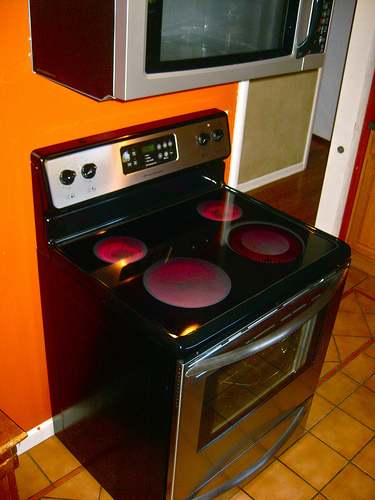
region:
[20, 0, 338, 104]
a microwave oven is mounted above the range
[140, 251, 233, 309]
the burners are a smooth surface which simplifies the top cooking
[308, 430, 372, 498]
the floor is tiled or linoleum yellow in color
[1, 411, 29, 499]
the corner of a wooden table sits next to the stove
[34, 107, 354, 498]
a range sits all the kitchen floor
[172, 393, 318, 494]
a sliding toward the bottom of the range allows for storage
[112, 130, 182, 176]
a modern console the range featuring digital readout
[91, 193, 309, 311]
the 4 burners on top of the range are still hot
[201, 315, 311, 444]
a glass door in front of the stove door allows you to see and while cooking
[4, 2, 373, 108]
microwave is mounted above stovetop range for easy cooking access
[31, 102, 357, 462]
black oven and stove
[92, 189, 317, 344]
electric stove top burners on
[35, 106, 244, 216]
control panel for stove and oven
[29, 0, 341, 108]
wall mounted microwave oven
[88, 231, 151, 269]
ceramic top electric range burner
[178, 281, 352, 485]
silver colored oven door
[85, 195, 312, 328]
four stove burners on electric stove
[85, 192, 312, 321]
range top with burners on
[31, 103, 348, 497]
electric stove with oven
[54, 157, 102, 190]
stove burner control knobs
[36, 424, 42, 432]
speck of orange paint on baseboard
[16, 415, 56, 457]
section of white baseboard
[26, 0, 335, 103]
Microwave oven mounted above stove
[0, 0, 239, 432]
wall is painted bright orange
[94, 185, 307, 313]
four stove burners with red glow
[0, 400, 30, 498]
corner of brown countertop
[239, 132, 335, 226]
wooden floor in hallway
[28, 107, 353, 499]
black and silver stove with oven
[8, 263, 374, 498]
terra cotta colored tile in kitchen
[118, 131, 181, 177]
control plate with clock on stove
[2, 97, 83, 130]
orange kitchen wall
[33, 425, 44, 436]
orange spot on the white baseboard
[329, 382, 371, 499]
tiled kitchen floor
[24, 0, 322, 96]
microwave above the stove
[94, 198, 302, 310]
four electric burners on a stove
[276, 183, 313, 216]
wooden floor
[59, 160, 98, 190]
two dials on the oven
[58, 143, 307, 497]
silver and black kitchen stove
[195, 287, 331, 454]
window on the oven door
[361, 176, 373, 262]
wooden kitchen cabinet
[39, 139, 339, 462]
black stove by orange wall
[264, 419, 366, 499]
tan tiles in kitchen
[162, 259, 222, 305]
hot burner of glass stove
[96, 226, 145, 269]
hot burner of glass stove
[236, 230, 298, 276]
hot burner of glass stove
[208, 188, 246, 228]
hot burner of glass stove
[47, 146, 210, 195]
stainless steel display area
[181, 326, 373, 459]
stainless steel oven on front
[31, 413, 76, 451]
white base boards on wall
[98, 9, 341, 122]
microwave above stove